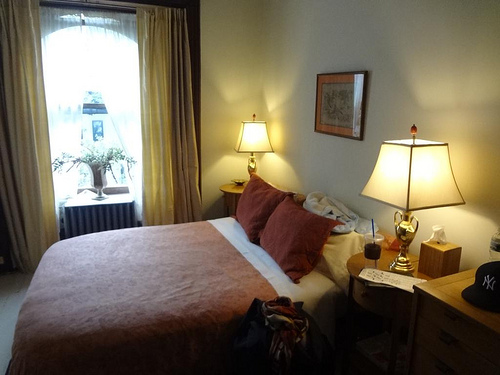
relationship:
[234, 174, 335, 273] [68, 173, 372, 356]
pillows on bed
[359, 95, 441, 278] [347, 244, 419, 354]
lamp on table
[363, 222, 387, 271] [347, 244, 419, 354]
cup on table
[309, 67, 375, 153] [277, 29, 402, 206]
painting on wall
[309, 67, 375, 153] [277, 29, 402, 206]
painting in wall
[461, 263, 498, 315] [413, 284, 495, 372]
cap on drawer